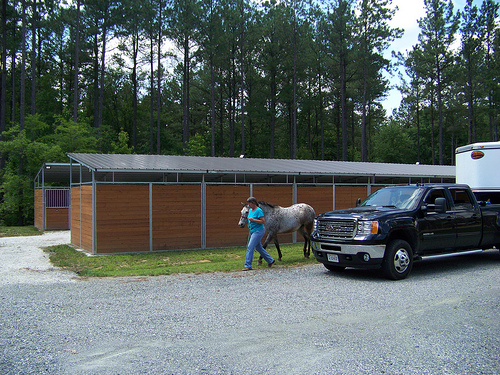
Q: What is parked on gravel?
A: A black truck.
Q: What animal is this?
A: A horse.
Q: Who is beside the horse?
A: The handler.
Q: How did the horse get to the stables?
A: In the trailer.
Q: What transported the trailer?
A: The black truck.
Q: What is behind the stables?
A: Tall pine trees.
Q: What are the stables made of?
A: Wood and metal.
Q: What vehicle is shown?
A: Truck.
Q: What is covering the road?
A: Gravel.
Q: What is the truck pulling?
A: Trailer.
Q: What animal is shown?
A: Horse.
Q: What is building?
A: Stables.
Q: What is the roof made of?
A: Metal.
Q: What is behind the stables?
A: Trees.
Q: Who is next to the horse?
A: A woman.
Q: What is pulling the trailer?
A: Truck.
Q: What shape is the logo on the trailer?
A: Oval.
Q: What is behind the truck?
A: Trailer.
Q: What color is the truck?
A: Black.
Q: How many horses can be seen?
A: One.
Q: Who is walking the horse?
A: A woman.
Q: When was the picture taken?
A: Daytime.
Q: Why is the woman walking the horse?
A: Taking him to stables.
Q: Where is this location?
A: Stables.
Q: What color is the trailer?
A: White.